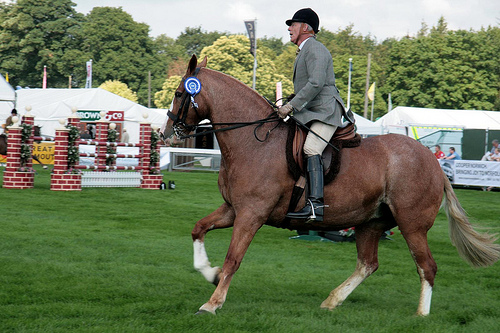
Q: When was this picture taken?
A: Daytime.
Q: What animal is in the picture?
A: Horse.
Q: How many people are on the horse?
A: 1.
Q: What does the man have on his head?
A: Derby hat.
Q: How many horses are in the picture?
A: 1.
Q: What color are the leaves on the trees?
A: Green.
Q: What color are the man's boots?
A: Black.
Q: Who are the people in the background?
A: Spectators.